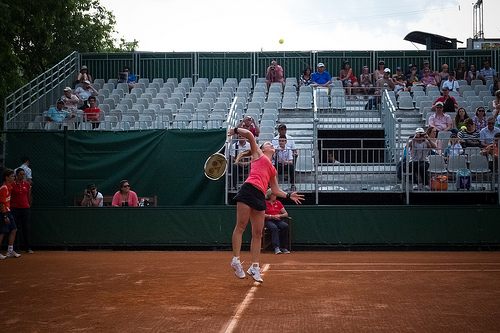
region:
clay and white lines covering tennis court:
[5, 250, 498, 330]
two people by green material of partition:
[0, 165, 495, 250]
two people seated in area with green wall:
[1, 125, 217, 202]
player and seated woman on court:
[200, 120, 492, 277]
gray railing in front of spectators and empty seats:
[225, 55, 490, 195]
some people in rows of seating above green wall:
[5, 60, 220, 130]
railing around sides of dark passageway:
[305, 80, 395, 180]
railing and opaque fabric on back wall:
[80, 40, 490, 75]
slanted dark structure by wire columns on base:
[400, 0, 495, 45]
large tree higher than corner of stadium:
[1, 0, 138, 101]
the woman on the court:
[200, 104, 286, 283]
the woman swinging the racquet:
[194, 117, 305, 295]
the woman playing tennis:
[192, 110, 311, 287]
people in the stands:
[274, 61, 463, 92]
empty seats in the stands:
[127, 85, 217, 121]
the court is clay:
[3, 251, 495, 331]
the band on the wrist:
[282, 190, 296, 199]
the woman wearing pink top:
[250, 148, 278, 200]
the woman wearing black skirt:
[225, 187, 273, 215]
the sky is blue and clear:
[151, 8, 405, 40]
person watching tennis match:
[44, 98, 73, 127]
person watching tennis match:
[78, 93, 108, 128]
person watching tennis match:
[56, 83, 86, 107]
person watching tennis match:
[73, 76, 108, 103]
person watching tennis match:
[72, 56, 100, 84]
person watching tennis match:
[259, 54, 289, 84]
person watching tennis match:
[109, 167, 144, 217]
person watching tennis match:
[67, 175, 108, 208]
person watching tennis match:
[403, 120, 434, 165]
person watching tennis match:
[423, 94, 458, 133]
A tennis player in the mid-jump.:
[198, 105, 312, 299]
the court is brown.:
[68, 253, 144, 311]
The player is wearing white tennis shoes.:
[220, 254, 269, 287]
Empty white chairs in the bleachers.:
[141, 81, 202, 128]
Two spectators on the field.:
[2, 162, 37, 264]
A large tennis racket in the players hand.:
[200, 136, 233, 186]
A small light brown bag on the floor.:
[430, 173, 450, 190]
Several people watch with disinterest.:
[401, 97, 498, 177]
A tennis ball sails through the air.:
[273, 34, 287, 47]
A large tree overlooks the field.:
[1, 0, 154, 119]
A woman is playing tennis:
[201, 122, 308, 285]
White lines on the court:
[214, 258, 498, 332]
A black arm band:
[231, 123, 241, 138]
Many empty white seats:
[138, 74, 263, 128]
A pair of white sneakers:
[227, 254, 266, 285]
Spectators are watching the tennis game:
[264, 56, 498, 176]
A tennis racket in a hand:
[200, 123, 240, 183]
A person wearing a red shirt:
[10, 165, 32, 210]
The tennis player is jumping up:
[200, 121, 305, 288]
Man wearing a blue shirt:
[309, 59, 333, 89]